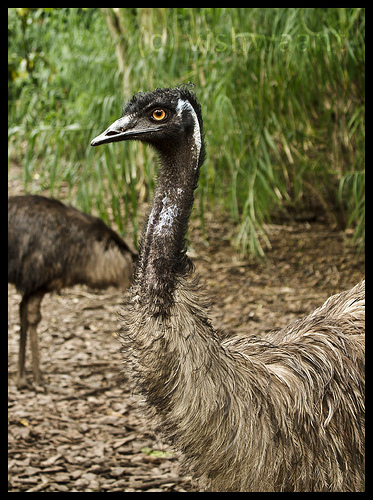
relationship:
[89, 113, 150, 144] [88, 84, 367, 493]
beak of bird